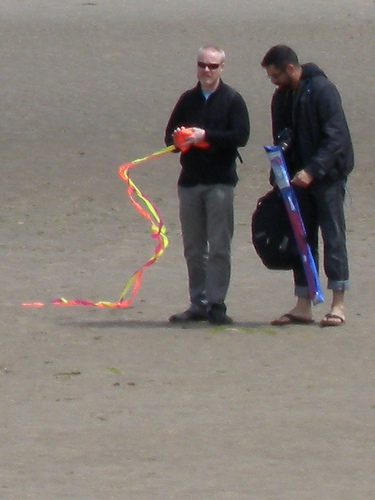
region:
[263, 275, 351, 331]
A man wearing sandles.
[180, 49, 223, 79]
A man wearing sunglasses.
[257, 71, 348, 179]
A man wearing a jacket.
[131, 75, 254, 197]
A man wearing a sweater.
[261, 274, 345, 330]
The man has two feet.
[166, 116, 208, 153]
The man has two hands.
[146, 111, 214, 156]
The man is holding an object.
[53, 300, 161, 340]
Shadow on the ground.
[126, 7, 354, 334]
Two people standing next to each other.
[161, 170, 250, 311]
The man is wearing pants.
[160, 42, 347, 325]
Two men standing in the open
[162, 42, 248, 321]
Man in black sweater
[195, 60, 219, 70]
Black sunglasses on the face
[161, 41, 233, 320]
Man wearing black sunglassess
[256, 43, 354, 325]
Man wearing brown sandals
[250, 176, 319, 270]
Black backpack in his hands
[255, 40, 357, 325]
Man carrying a backpack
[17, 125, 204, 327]
Colorful ribbons blowing in the wind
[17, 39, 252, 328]
Man is holding ribbons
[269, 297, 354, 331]
A pair of brown sandals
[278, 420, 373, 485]
gray sand make up the beach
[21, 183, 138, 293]
sand is cement colored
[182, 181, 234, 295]
man is wearing gray slacks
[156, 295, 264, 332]
man is weARING black and grey socks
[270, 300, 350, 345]
guy is wearing brown sandals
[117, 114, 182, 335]
man is holding colorful and long ribbon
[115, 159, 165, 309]
ribbon is yellow and orange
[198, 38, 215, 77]
man is wearing sunglasses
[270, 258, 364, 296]
man jeans are cuffed over ankles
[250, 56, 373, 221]
guy is wearing black hooded jacket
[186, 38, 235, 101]
a man in sunglasses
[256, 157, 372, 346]
a man wearing flip flops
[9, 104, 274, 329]
toy with orange and yellow streamers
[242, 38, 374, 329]
a mna holding a backpack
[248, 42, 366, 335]
a man with rolled up jeans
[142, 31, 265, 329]
a man with grey pants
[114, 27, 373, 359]
two men on a beach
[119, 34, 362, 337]
a young man and an old man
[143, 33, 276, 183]
a man who is balding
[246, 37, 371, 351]
a man wearing a coat and flip flops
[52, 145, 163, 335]
green and orange streamers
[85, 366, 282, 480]
ground covered in sand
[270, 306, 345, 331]
pair of brown sandals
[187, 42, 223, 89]
man in black sun glasses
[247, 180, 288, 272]
black backpack being held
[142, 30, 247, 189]
man in black shirt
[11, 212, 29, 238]
grey rock laying on ground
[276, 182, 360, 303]
pants with legs rolled up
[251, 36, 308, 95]
man with eye glasses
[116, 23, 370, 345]
two people standing side by side